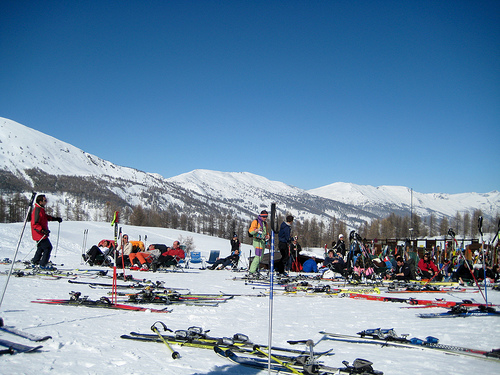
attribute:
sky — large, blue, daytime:
[1, 0, 500, 194]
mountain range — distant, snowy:
[0, 116, 499, 241]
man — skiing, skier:
[31, 194, 62, 270]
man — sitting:
[206, 249, 239, 270]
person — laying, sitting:
[129, 244, 162, 272]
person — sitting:
[82, 240, 110, 267]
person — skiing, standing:
[248, 210, 270, 277]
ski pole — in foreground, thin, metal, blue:
[268, 203, 280, 375]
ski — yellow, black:
[120, 335, 322, 363]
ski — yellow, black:
[130, 331, 334, 355]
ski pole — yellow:
[151, 321, 181, 361]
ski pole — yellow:
[252, 344, 304, 375]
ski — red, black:
[29, 300, 173, 313]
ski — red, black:
[37, 298, 168, 312]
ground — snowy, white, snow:
[0, 221, 499, 375]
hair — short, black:
[36, 194, 46, 204]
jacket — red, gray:
[31, 202, 54, 241]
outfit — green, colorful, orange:
[249, 217, 271, 273]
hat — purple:
[259, 210, 269, 217]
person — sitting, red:
[152, 240, 185, 272]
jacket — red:
[162, 246, 184, 261]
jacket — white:
[140, 248, 161, 261]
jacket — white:
[98, 246, 110, 255]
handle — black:
[270, 203, 276, 231]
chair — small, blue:
[186, 251, 204, 268]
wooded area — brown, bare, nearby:
[1, 192, 500, 250]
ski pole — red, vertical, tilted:
[447, 228, 486, 303]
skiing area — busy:
[0, 220, 499, 374]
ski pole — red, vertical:
[118, 226, 126, 280]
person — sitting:
[107, 234, 132, 268]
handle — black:
[448, 230, 454, 238]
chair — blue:
[203, 250, 219, 267]